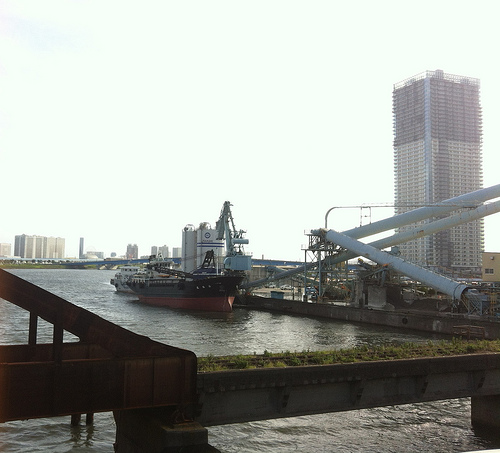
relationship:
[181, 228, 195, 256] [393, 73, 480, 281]
walls on building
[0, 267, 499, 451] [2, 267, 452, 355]
bridge near water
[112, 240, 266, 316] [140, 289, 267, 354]
boat on water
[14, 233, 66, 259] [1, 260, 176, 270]
building on land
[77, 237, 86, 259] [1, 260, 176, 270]
building on land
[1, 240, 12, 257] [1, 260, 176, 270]
building on land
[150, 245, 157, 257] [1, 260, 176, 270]
building on land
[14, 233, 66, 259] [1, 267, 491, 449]
building across water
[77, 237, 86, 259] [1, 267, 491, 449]
building across water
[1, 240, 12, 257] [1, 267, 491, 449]
building across water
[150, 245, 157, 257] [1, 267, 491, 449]
building across water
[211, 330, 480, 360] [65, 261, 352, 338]
land across water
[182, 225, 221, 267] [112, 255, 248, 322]
building near boat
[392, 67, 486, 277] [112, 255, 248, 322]
building near boat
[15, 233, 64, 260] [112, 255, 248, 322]
building near boat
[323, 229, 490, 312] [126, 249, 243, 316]
white pole near boat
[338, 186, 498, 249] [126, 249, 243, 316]
white tubes near boat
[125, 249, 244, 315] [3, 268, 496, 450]
boat in river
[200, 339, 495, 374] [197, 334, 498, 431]
plants growing on bridge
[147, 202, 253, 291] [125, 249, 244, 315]
concrete plant by boat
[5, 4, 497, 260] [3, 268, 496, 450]
sky above river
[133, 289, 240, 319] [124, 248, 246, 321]
bottom on ship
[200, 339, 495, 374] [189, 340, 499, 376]
plants on passway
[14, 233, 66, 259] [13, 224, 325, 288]
building in background